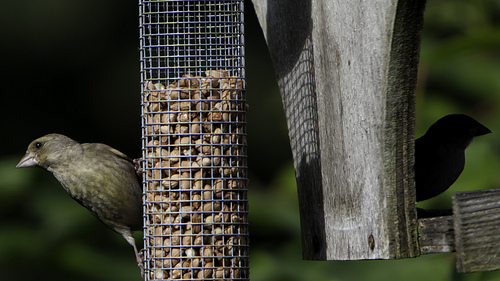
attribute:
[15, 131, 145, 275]
bird — clinging, perching, brown, looking, sitting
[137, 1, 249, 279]
bird feeder — wire, cylinder, filled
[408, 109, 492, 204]
shadow — small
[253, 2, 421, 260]
gray — the color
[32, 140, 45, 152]
eye — black in color, black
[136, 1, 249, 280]
tube — chain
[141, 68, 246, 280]
beans — brown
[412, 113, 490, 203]
bird — black, perched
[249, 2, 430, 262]
plank — gray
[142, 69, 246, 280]
feed — inside, for bird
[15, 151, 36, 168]
beak — white, pointy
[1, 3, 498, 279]
foilage — green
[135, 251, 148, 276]
talon — pink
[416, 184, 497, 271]
bracket feeder — wood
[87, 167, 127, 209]
belly — yellow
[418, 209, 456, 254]
holder — wooden